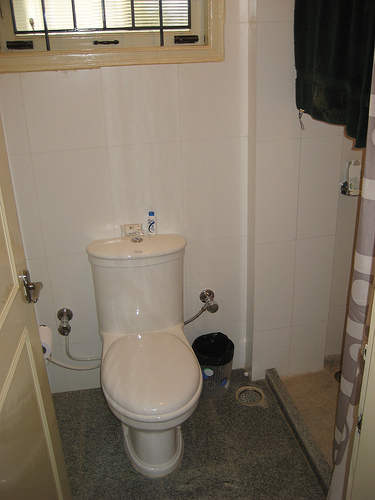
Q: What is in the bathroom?
A: Black towel.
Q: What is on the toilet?
A: Oval lid.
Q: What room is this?
A: Bathroom.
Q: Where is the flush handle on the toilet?
A: On top of the tank.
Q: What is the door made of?
A: Wood.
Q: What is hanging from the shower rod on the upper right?
A: Towel.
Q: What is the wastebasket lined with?
A: Plastic bag.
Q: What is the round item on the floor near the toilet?
A: Drain.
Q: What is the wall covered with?
A: Tiles.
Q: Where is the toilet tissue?
A: To the left of the toilet on the wall.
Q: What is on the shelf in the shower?
A: Shampoo.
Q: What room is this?
A: Bathroom.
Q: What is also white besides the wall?
A: The toilet.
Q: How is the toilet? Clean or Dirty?
A: Clean.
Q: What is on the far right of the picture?
A: Shower Curtain.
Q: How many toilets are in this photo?
A: One.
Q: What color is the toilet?
A: White.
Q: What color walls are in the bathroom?
A: White.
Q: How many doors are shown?
A: One.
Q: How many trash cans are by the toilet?
A: One.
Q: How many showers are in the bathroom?
A: One.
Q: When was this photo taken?
A: Daytime.